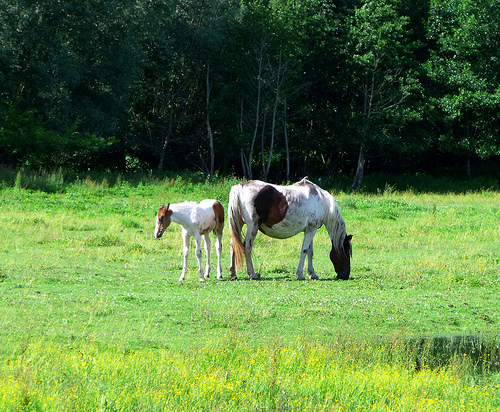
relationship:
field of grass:
[1, 173, 498, 409] [0, 176, 499, 408]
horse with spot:
[215, 172, 364, 284] [247, 176, 297, 236]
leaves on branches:
[0, 2, 496, 144] [204, 71, 298, 173]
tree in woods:
[337, 10, 498, 175] [3, 41, 496, 203]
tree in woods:
[0, 0, 499, 186] [3, 41, 496, 203]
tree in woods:
[0, 0, 499, 186] [1, 0, 498, 170]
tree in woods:
[0, 0, 499, 186] [0, 0, 494, 203]